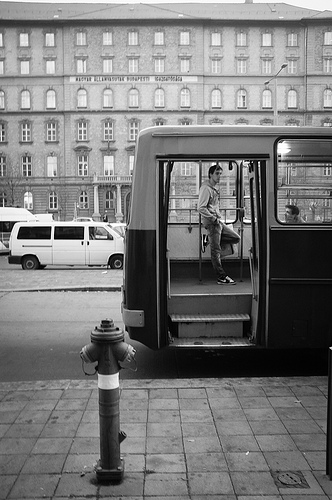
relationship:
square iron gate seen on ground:
[274, 469, 309, 492] [4, 379, 327, 500]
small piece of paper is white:
[245, 449, 251, 457] [97, 371, 121, 394]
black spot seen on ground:
[53, 415, 60, 425] [4, 379, 327, 500]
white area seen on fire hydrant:
[97, 371, 121, 394] [78, 317, 140, 488]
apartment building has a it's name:
[0, 0, 331, 241] [75, 74, 183, 83]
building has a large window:
[0, 0, 331, 241] [76, 147, 91, 179]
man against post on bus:
[195, 163, 240, 285] [190, 163, 208, 285]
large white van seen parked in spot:
[7, 222, 129, 271] [2, 262, 127, 276]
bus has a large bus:
[119, 117, 332, 355] [119, 117, 332, 355]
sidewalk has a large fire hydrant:
[3, 379, 332, 496] [78, 317, 140, 488]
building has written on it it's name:
[0, 0, 331, 241] [69, 72, 200, 86]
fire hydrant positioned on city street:
[78, 317, 140, 488] [0, 253, 174, 378]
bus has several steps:
[119, 117, 332, 355] [171, 287, 253, 349]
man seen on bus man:
[279, 200, 311, 227] [283, 202, 307, 227]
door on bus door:
[155, 155, 267, 356] [155, 155, 267, 353]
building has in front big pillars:
[0, 0, 331, 241] [91, 182, 129, 227]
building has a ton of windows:
[0, 0, 331, 241] [5, 29, 331, 209]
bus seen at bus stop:
[119, 117, 332, 355] [120, 128, 329, 376]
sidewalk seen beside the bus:
[3, 379, 332, 496] [2, 352, 332, 406]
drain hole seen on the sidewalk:
[273, 469, 312, 491] [3, 379, 332, 496]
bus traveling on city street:
[119, 117, 332, 355] [0, 253, 174, 378]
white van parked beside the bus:
[7, 222, 129, 271] [122, 114, 331, 375]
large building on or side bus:
[0, 0, 331, 241] [119, 117, 332, 355]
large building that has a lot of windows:
[0, 0, 331, 241] [5, 29, 331, 209]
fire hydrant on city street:
[78, 317, 140, 488] [4, 379, 327, 500]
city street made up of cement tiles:
[4, 379, 327, 500] [5, 380, 331, 498]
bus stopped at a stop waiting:
[119, 117, 332, 355] [124, 117, 330, 380]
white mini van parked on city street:
[7, 222, 129, 271] [2, 263, 134, 274]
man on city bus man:
[195, 163, 240, 285] [195, 163, 240, 285]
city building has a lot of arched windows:
[0, 0, 331, 241] [5, 29, 331, 209]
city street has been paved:
[0, 253, 174, 378] [4, 291, 332, 382]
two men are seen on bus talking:
[199, 166, 308, 284] [197, 165, 309, 294]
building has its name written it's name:
[0, 0, 331, 241] [75, 74, 183, 83]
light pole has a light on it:
[261, 61, 293, 128] [262, 58, 292, 90]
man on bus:
[195, 163, 246, 285] [119, 117, 332, 355]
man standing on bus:
[195, 163, 240, 285] [119, 117, 332, 355]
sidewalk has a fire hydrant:
[3, 379, 332, 496] [78, 317, 140, 488]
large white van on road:
[7, 222, 129, 271] [3, 260, 135, 270]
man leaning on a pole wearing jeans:
[195, 163, 246, 285] [204, 225, 247, 283]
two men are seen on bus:
[199, 166, 308, 284] [119, 117, 332, 355]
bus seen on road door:
[119, 117, 332, 355] [155, 155, 267, 353]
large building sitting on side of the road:
[0, 0, 331, 241] [2, 248, 324, 286]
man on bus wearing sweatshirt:
[195, 163, 246, 285] [198, 178, 224, 227]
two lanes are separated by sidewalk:
[1, 230, 332, 391] [3, 379, 332, 496]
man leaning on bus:
[195, 163, 240, 285] [109, 100, 322, 326]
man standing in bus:
[195, 163, 240, 285] [123, 126, 317, 379]